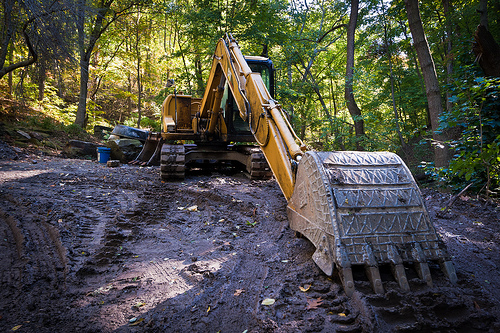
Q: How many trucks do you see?
A: 1 truck.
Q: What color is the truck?
A: The truck is yellow.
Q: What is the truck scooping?
A: The dirt.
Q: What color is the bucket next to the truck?
A: It is blue.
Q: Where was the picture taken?
A: In the forest.